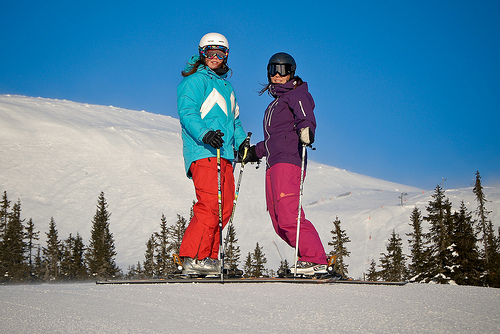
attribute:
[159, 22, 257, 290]
woman — wearing, skiing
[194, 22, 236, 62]
helmet — white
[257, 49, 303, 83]
helmet — black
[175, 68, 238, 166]
jacket — green, blue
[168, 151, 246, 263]
pant — red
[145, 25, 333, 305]
women — skier, skiing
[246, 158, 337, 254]
pant — pink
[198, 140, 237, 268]
pole — ski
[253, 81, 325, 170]
jacket — purple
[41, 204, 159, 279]
tree — green, pine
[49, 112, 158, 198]
snow — covered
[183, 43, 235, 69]
goggle — ski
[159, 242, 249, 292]
boot — snow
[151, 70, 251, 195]
coat — blue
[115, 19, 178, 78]
sky — blue